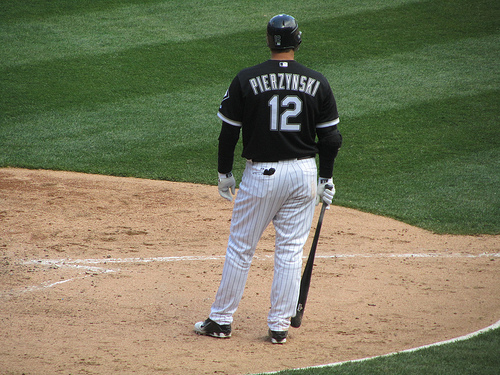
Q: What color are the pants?
A: White.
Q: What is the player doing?
A: Standing.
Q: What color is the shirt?
A: Black.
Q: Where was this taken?
A: Baseball field.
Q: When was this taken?
A: During a baseball game.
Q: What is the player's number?
A: 12.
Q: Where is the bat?
A: In the player's right hand.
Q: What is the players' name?
A: Pierzynski.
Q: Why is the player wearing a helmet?
A: Safety.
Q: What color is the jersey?
A: Black.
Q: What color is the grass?
A: Green.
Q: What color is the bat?
A: Black.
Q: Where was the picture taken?
A: On a baseball field.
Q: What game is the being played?
A: Baseball.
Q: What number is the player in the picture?
A: 12.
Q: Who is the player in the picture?
A: Pierzynski.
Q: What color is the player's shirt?
A: Black.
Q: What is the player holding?
A: A bat.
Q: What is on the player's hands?
A: Gloves.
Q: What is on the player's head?
A: A helmet.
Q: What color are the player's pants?
A: White.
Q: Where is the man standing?
A: In dirt.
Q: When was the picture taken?
A: Daytime.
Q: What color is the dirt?
A: Brown.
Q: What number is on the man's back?
A: 12.